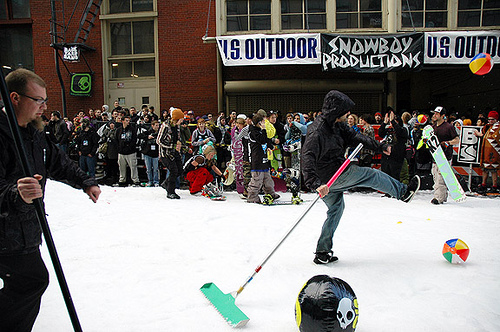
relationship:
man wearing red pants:
[184, 143, 227, 201] [185, 165, 215, 195]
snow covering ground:
[31, 180, 497, 330] [31, 177, 499, 328]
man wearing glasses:
[2, 68, 102, 330] [21, 91, 50, 107]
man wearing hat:
[155, 100, 188, 197] [168, 104, 183, 120]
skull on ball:
[335, 296, 355, 330] [294, 270, 363, 330]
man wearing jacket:
[297, 83, 424, 264] [298, 84, 386, 189]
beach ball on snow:
[441, 238, 469, 267] [31, 180, 497, 330]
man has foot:
[297, 83, 424, 264] [395, 170, 424, 203]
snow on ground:
[31, 180, 497, 330] [31, 177, 499, 328]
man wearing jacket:
[297, 83, 424, 264] [298, 90, 377, 192]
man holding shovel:
[297, 83, 424, 264] [199, 141, 365, 330]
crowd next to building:
[36, 97, 497, 193] [4, 3, 499, 129]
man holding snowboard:
[423, 103, 463, 203] [420, 124, 466, 204]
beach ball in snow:
[441, 238, 469, 267] [31, 180, 497, 330]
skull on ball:
[335, 296, 355, 330] [294, 275, 360, 330]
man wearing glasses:
[2, 68, 102, 330] [16, 90, 52, 106]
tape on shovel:
[327, 158, 350, 188] [199, 141, 365, 330]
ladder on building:
[43, 0, 104, 54] [26, 0, 498, 122]